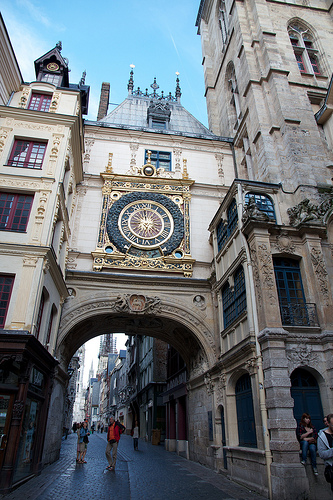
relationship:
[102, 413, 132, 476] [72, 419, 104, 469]
man standing in front woman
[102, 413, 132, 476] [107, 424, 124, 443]
man wearing shirt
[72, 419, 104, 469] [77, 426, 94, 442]
woman wearing shirt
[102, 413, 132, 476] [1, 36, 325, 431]
man under building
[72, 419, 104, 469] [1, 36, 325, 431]
woman under building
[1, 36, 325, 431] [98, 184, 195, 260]
building has a clock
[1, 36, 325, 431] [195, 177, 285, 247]
building has balcony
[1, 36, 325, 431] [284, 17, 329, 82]
building has a window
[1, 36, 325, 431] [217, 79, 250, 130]
building has a window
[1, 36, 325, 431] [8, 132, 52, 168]
building has a window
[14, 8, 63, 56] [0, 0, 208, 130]
cloud in cloud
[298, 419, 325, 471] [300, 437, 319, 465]
woman wearing jeans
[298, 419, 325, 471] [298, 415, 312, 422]
woman has brown hair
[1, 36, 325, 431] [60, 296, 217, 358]
building has arch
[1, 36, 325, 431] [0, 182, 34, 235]
building has window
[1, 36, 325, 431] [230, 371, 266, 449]
building has window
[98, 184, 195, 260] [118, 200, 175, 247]
clock has gold face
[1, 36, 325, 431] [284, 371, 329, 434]
building has window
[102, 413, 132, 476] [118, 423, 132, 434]
man wearing a backpack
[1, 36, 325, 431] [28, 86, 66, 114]
building has window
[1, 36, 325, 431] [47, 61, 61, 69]
building has clock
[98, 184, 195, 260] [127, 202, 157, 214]
clock has roman numerals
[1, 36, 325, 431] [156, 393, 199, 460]
building has doors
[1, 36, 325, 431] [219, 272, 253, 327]
building has window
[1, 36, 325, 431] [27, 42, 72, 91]
building has a tower